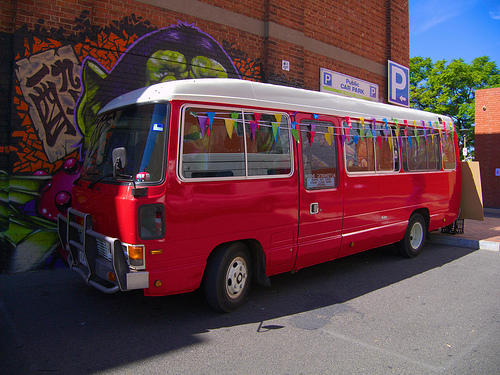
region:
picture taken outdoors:
[35, 31, 465, 265]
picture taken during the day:
[50, 27, 480, 312]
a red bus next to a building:
[34, 25, 486, 357]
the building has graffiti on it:
[65, 27, 277, 50]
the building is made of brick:
[68, 36, 274, 48]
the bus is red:
[152, 137, 488, 277]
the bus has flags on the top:
[187, 100, 488, 169]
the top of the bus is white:
[195, 92, 491, 172]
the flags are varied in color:
[193, 76, 480, 170]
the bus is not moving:
[101, 190, 460, 346]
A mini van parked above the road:
[75, 75, 497, 306]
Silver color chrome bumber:
[51, 207, 128, 297]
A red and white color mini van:
[5, 74, 441, 302]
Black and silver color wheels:
[216, 213, 436, 314]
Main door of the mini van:
[291, 114, 368, 280]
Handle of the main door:
[305, 200, 336, 220]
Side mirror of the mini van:
[111, 143, 156, 203]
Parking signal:
[386, 45, 416, 106]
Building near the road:
[18, 6, 448, 65]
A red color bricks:
[291, 2, 431, 59]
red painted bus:
[52, 56, 492, 326]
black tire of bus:
[191, 228, 299, 327]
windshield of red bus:
[64, 96, 196, 195]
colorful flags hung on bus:
[178, 94, 473, 173]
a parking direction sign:
[374, 53, 443, 118]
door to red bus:
[283, 103, 366, 279]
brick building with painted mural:
[9, 11, 430, 165]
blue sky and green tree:
[403, 2, 498, 142]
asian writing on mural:
[11, 43, 100, 163]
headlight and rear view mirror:
[97, 137, 187, 252]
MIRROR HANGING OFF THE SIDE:
[105, 147, 130, 175]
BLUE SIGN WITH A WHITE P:
[390, 63, 410, 103]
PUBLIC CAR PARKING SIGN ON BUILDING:
[320, 70, 373, 92]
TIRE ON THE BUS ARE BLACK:
[229, 251, 239, 256]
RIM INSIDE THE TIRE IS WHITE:
[232, 271, 246, 275]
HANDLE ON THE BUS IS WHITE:
[308, 199, 320, 212]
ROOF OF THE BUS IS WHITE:
[272, 86, 307, 106]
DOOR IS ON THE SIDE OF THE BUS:
[300, 114, 345, 257]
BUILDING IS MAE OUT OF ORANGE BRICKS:
[337, 25, 357, 36]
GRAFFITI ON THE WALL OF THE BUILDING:
[32, 80, 100, 109]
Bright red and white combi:
[50, 64, 472, 307]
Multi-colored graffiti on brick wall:
[6, 3, 59, 273]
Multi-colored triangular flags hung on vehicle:
[171, 100, 466, 145]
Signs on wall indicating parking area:
[308, 50, 418, 119]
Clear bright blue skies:
[404, 1, 498, 57]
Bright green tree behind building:
[408, 46, 498, 154]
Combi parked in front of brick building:
[14, 3, 489, 334]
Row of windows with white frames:
[168, 94, 465, 188]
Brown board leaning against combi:
[450, 147, 491, 239]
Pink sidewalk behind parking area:
[407, 196, 499, 257]